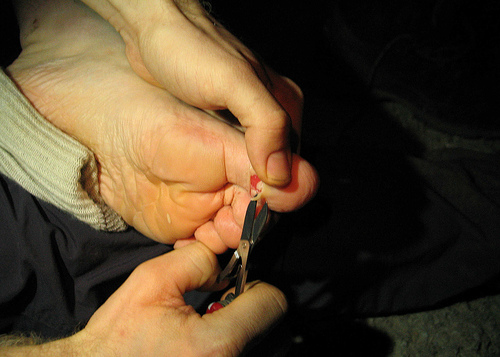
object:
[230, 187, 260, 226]
toe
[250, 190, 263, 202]
skin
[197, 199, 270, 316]
metal instrument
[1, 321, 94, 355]
hairs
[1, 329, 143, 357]
arm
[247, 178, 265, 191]
wound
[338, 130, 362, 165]
ground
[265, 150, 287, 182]
finger nail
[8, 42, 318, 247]
foot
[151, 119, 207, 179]
skin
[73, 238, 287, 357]
hand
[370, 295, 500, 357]
carpet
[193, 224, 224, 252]
toes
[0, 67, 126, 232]
cloth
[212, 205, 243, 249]
toe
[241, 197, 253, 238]
blades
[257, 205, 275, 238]
blades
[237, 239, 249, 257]
hinge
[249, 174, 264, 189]
hole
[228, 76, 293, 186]
thumb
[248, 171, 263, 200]
skin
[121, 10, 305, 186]
hand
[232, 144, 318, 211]
toe